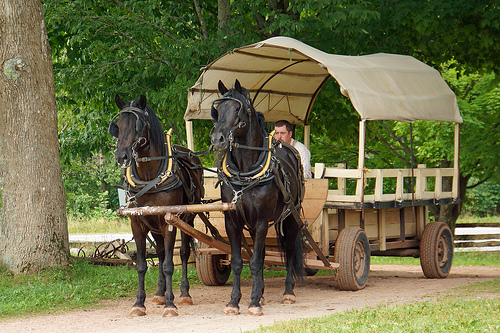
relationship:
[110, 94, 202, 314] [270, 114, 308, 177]
horse in front of man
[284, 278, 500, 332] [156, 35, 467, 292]
grass near carriage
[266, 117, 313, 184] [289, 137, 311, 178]
man wearing shirt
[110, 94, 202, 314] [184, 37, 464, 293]
horse pulling carriage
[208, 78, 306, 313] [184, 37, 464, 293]
horse pulling carriage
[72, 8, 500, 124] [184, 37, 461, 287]
tree behind carriage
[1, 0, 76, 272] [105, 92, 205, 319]
tree next horse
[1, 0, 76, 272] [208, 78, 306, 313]
tree next horse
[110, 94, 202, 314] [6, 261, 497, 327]
horse on path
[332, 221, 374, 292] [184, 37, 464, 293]
wheel on carriage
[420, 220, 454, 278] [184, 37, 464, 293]
wheel on carriage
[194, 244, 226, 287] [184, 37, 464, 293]
wheel on carriage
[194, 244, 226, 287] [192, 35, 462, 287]
wheel on wagon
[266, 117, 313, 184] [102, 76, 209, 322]
man rides horse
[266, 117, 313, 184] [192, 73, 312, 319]
man rides horse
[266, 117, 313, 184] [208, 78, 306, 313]
man rides horse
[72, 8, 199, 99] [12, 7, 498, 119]
tree on background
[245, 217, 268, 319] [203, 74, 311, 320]
leg of a horse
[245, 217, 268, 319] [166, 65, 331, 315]
leg of horse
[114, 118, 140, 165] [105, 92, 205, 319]
face of a horse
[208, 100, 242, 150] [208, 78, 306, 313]
face of a horse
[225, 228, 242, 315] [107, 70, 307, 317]
leg of horses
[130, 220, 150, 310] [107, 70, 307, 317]
leg of horses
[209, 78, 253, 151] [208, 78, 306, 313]
head of horse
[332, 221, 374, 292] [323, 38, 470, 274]
wheel of carriage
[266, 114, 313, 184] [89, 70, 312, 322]
man behind horses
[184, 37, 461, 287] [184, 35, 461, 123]
carriage with canopy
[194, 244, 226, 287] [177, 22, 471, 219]
wheel visible on carriage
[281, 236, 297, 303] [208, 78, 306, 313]
leg of horse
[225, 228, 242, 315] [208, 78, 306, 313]
leg of horse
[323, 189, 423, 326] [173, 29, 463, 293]
wheel on a wagon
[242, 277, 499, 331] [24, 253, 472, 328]
grass in field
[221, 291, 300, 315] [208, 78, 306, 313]
hooves of horse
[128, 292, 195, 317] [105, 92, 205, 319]
hooves of horse